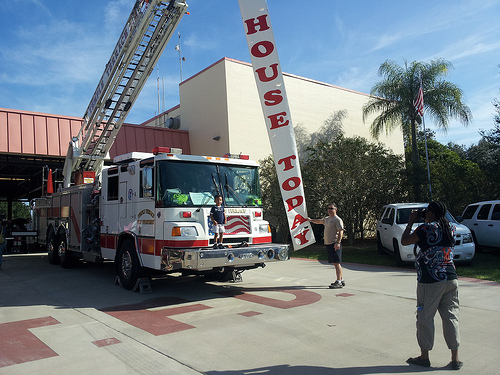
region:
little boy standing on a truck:
[202, 190, 247, 272]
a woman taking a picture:
[383, 181, 481, 371]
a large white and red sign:
[240, 15, 325, 257]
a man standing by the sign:
[295, 182, 363, 309]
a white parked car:
[370, 187, 490, 277]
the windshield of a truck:
[133, 151, 270, 208]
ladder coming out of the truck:
[66, 1, 195, 193]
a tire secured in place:
[95, 221, 162, 299]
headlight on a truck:
[164, 220, 200, 238]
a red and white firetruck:
[7, 120, 317, 299]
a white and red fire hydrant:
[29, 6, 279, 284]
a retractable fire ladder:
[56, 2, 185, 177]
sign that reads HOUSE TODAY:
[231, 4, 317, 252]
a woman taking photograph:
[394, 187, 473, 369]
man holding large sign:
[241, 7, 355, 292]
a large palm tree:
[359, 58, 470, 226]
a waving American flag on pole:
[407, 68, 432, 195]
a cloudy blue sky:
[2, 0, 492, 139]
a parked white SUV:
[377, 200, 479, 269]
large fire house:
[3, 56, 413, 249]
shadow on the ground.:
[264, 353, 353, 373]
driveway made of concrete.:
[241, 312, 323, 341]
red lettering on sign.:
[280, 156, 314, 236]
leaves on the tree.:
[380, 62, 453, 109]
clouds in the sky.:
[347, 31, 371, 80]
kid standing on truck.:
[210, 192, 227, 247]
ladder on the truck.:
[100, 12, 156, 110]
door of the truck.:
[141, 167, 153, 248]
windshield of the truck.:
[231, 168, 253, 193]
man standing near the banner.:
[323, 204, 353, 285]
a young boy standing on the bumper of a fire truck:
[209, 193, 228, 248]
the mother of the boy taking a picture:
[399, 199, 464, 369]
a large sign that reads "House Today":
[242, 1, 317, 251]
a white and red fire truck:
[29, 146, 292, 293]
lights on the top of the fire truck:
[150, 145, 250, 160]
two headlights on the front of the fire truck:
[171, 222, 270, 234]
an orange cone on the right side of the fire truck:
[44, 168, 54, 194]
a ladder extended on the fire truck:
[64, 0, 189, 168]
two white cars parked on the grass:
[372, 199, 499, 263]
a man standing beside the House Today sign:
[282, 200, 344, 288]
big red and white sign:
[218, 0, 370, 255]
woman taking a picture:
[385, 175, 478, 367]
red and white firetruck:
[13, 100, 317, 300]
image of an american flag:
[203, 204, 258, 244]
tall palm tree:
[347, 22, 469, 231]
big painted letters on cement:
[0, 227, 323, 367]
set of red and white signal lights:
[140, 133, 257, 168]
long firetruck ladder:
[21, 0, 186, 208]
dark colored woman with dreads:
[387, 187, 481, 368]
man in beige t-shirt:
[302, 193, 353, 274]